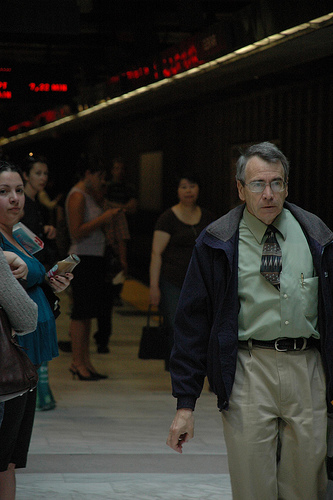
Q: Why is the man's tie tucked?
A: For safety.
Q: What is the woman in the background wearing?
A: T-shirt.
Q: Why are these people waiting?
A: For a train.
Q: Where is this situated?
A: Train station.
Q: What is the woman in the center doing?
A: Reading.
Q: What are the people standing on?
A: Stone floor.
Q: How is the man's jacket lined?
A: Grey pads.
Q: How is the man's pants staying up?
A: Belt.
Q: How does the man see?
A: With glasses.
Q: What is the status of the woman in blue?
A: Pregnant.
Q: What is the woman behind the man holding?
A: A purse.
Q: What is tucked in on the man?
A: A tie.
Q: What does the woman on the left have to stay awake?
A: Coffee.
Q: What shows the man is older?
A: His grey hair.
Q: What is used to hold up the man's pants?
A: A belt.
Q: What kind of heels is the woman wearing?
A: Black heels.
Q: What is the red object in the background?
A: LED lights.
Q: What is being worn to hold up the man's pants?
A: A belt.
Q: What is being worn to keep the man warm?
A: A jacket.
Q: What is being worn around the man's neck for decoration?
A: A tie.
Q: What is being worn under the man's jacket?
A: A green shirt.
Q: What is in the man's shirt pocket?
A: A pen.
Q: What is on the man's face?
A: Glasses.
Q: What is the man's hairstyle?
A: Short and gray.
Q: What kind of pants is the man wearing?
A: Khaki.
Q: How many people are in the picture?
A: Nine.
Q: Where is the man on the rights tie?
A: Around his neck.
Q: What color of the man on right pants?
A: Khaki.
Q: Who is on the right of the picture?
A: Man in khaki pants.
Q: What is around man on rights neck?
A: A tie.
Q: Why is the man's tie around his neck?
A: It's worn there.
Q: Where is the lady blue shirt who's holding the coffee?
A: The left side.